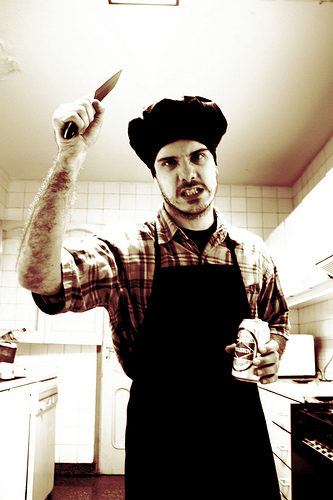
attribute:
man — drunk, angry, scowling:
[15, 93, 292, 499]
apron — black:
[122, 222, 282, 499]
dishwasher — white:
[26, 384, 61, 499]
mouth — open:
[179, 184, 204, 199]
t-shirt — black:
[178, 222, 219, 251]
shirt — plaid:
[29, 203, 290, 382]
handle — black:
[62, 102, 98, 142]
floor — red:
[47, 474, 125, 499]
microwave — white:
[276, 332, 316, 377]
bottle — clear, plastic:
[2, 327, 27, 378]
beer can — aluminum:
[230, 316, 272, 384]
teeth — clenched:
[185, 189, 201, 197]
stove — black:
[290, 401, 332, 499]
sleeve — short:
[32, 234, 122, 318]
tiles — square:
[0, 136, 333, 379]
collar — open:
[155, 206, 231, 252]